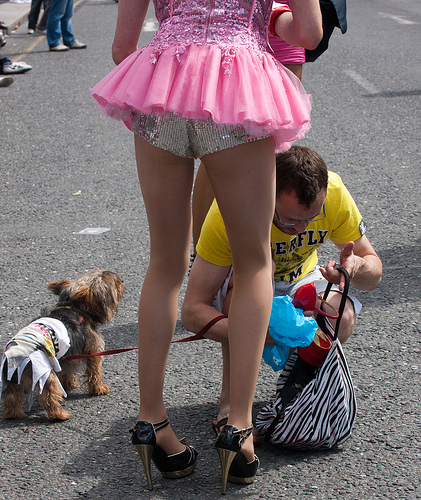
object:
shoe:
[211, 423, 260, 494]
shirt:
[0, 314, 71, 394]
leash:
[60, 314, 229, 362]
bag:
[253, 264, 358, 453]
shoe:
[293, 280, 339, 365]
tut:
[85, 27, 312, 157]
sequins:
[158, 118, 174, 137]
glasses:
[280, 212, 328, 228]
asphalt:
[29, 197, 54, 232]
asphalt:
[56, 209, 122, 257]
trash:
[75, 221, 118, 241]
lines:
[3, 0, 81, 78]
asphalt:
[3, 84, 74, 129]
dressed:
[3, 315, 70, 393]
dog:
[3, 267, 123, 422]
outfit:
[0, 316, 71, 394]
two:
[128, 411, 262, 491]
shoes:
[129, 421, 200, 493]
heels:
[133, 445, 153, 491]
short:
[130, 91, 277, 160]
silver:
[130, 108, 272, 159]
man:
[180, 143, 383, 447]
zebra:
[255, 335, 358, 450]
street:
[0, 16, 417, 500]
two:
[134, 125, 277, 490]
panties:
[131, 101, 271, 161]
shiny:
[148, 112, 162, 139]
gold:
[218, 449, 234, 493]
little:
[4, 272, 125, 425]